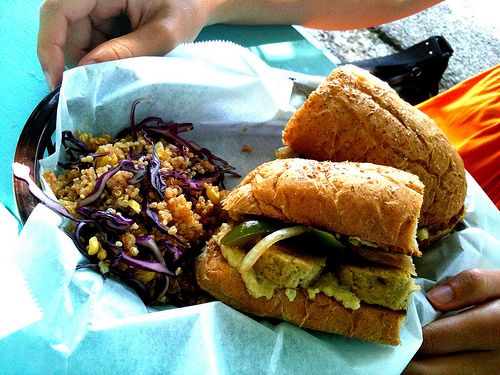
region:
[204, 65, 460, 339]
two halves of sandwich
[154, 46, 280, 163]
white paper under food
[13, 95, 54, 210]
edge of brown food basket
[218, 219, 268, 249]
sliced green pepper skin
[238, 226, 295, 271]
thin slice of onion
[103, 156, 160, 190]
slices of purple cabbage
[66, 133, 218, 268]
pile of quinoa in basket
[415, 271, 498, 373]
fingers on white paper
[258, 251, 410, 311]
meat inside of sandwich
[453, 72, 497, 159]
wrinkles on orange shirt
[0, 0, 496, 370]
light green table with food on it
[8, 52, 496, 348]
black plastic food basket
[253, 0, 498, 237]
gray wooden bench next to table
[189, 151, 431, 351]
half of sandwich with wheat bread onions and peppers on it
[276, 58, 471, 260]
half of sandwich with wheat bread onions and peppers on it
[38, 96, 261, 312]
side order of yellow corn with purple cabbage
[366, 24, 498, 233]
orange clothing worn by person eating food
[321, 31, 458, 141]
small black purse or bag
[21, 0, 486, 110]
right arm of person holding food basket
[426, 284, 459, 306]
short nail on finger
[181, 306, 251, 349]
creases in white paper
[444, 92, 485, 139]
edge of orange dress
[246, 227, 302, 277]
sliver of white onion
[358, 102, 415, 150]
sesame seeds on top of bun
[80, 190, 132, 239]
crisp cuts on purple cabbage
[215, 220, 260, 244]
shiny slice of green pepper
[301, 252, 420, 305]
large chunk of yellow hummus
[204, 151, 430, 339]
large slice of sandwich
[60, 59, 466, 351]
basket filled with food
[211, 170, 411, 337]
half sandwich on plate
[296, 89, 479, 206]
half sandwich on plate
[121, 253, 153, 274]
red cabbage in cous cous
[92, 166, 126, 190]
red cabbage in cous cous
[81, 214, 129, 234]
red cabbage in cous cous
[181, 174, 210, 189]
red cabbage in cous cous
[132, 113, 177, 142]
red cabbage in cous cous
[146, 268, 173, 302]
red cabbage in cous cous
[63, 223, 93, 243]
red cabbage in cous cous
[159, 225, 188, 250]
red cabbage in cous cous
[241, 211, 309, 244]
Green pepper on sandwich.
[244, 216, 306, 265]
White onion slice on top of sandwich.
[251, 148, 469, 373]
Sandwich on wheat hoagie bun.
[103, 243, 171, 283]
Piece of purple cabbage on food.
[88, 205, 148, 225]
Piece of purple cabbage on food.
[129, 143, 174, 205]
Piece of purple cabbage on food.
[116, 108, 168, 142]
Piece of purple cabbage on food.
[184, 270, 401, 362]
Sandwich sitting on white paper.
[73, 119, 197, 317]
Brown and purple food sitting on white paper.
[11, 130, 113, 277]
White paper inside of brown basket.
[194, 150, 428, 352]
sandwich cut in half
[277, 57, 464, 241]
sandwich cut in half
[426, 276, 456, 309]
fingernail belongs to finger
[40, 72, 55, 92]
fingernail belongs to finger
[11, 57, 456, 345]
food holds plate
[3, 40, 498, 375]
paper underneath food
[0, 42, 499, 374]
paper on top of plate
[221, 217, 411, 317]
food inside bun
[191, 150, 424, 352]
bun surrounds food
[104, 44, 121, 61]
wrinkle part of finger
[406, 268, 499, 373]
person's hand under plate